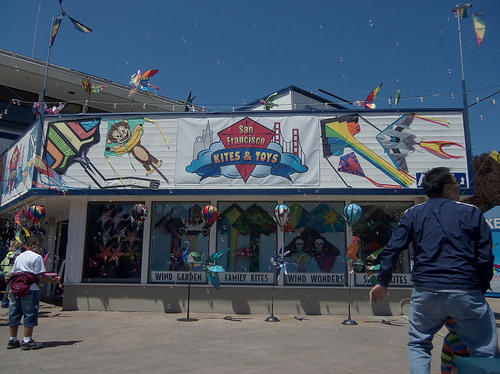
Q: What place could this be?
A: It is a store.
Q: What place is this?
A: It is a store.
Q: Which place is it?
A: It is a store.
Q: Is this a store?
A: Yes, it is a store.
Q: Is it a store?
A: Yes, it is a store.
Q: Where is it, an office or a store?
A: It is a store.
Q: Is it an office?
A: No, it is a store.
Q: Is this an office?
A: No, it is a store.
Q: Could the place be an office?
A: No, it is a store.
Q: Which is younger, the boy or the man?
A: The boy is younger than the man.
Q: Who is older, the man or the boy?
A: The man is older than the boy.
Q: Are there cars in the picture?
A: No, there are no cars.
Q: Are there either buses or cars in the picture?
A: No, there are no cars or buses.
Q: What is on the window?
A: The sign is on the window.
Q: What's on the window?
A: The sign is on the window.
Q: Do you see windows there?
A: Yes, there is a window.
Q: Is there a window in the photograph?
A: Yes, there is a window.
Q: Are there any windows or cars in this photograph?
A: Yes, there is a window.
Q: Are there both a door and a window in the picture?
A: Yes, there are both a window and a door.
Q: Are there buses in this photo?
A: No, there are no buses.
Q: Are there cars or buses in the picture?
A: No, there are no buses or cars.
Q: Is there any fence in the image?
A: No, there are no fences.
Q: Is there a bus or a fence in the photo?
A: No, there are no fences or buses.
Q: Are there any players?
A: No, there are no players.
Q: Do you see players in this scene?
A: No, there are no players.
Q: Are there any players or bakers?
A: No, there are no players or bakers.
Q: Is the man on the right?
A: Yes, the man is on the right of the image.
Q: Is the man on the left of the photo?
A: No, the man is on the right of the image.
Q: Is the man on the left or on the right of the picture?
A: The man is on the right of the image.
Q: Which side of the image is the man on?
A: The man is on the right of the image.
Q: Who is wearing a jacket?
A: The man is wearing a jacket.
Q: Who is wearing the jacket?
A: The man is wearing a jacket.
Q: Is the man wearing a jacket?
A: Yes, the man is wearing a jacket.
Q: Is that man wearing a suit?
A: No, the man is wearing a jacket.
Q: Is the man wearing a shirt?
A: Yes, the man is wearing a shirt.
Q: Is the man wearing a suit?
A: No, the man is wearing a shirt.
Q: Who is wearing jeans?
A: The man is wearing jeans.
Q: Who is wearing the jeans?
A: The man is wearing jeans.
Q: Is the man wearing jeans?
A: Yes, the man is wearing jeans.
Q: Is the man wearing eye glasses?
A: No, the man is wearing jeans.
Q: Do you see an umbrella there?
A: No, there are no umbrellas.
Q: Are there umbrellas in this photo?
A: No, there are no umbrellas.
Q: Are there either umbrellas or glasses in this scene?
A: No, there are no umbrellas or glasses.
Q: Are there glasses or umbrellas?
A: No, there are no umbrellas or glasses.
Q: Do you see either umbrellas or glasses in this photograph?
A: No, there are no umbrellas or glasses.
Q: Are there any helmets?
A: No, there are no helmets.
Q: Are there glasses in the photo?
A: No, there are no glasses.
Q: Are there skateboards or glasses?
A: No, there are no glasses or skateboards.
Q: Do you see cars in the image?
A: No, there are no cars.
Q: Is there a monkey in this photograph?
A: Yes, there is a monkey.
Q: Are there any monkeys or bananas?
A: Yes, there is a monkey.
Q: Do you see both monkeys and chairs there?
A: No, there is a monkey but no chairs.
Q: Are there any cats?
A: No, there are no cats.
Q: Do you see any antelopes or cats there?
A: No, there are no cats or antelopes.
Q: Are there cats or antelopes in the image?
A: No, there are no cats or antelopes.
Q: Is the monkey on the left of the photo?
A: Yes, the monkey is on the left of the image.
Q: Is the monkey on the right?
A: No, the monkey is on the left of the image.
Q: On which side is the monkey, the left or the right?
A: The monkey is on the left of the image.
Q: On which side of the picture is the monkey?
A: The monkey is on the left of the image.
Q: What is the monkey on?
A: The monkey is on the sign.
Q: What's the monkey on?
A: The monkey is on the sign.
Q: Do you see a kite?
A: Yes, there is a kite.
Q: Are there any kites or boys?
A: Yes, there is a kite.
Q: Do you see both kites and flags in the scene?
A: Yes, there are both a kite and a flag.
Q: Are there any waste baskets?
A: No, there are no waste baskets.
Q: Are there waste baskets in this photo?
A: No, there are no waste baskets.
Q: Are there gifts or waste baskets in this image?
A: No, there are no waste baskets or gifts.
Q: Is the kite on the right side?
A: Yes, the kite is on the right of the image.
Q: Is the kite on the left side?
A: No, the kite is on the right of the image.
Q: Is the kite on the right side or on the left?
A: The kite is on the right of the image.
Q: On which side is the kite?
A: The kite is on the right of the image.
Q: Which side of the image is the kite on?
A: The kite is on the right of the image.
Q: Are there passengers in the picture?
A: No, there are no passengers.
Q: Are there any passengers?
A: No, there are no passengers.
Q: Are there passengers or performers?
A: No, there are no passengers or performers.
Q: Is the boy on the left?
A: Yes, the boy is on the left of the image.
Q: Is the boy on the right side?
A: No, the boy is on the left of the image.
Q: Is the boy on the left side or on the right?
A: The boy is on the left of the image.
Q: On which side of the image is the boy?
A: The boy is on the left of the image.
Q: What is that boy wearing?
A: The boy is wearing a shirt.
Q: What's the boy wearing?
A: The boy is wearing a shirt.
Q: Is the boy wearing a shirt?
A: Yes, the boy is wearing a shirt.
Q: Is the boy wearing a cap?
A: No, the boy is wearing a shirt.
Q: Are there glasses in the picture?
A: No, there are no glasses.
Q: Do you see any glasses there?
A: No, there are no glasses.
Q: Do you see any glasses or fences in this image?
A: No, there are no glasses or fences.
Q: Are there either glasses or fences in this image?
A: No, there are no glasses or fences.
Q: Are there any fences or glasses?
A: No, there are no glasses or fences.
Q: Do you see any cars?
A: No, there are no cars.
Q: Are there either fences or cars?
A: No, there are no cars or fences.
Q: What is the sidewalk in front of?
A: The sidewalk is in front of the store.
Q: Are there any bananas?
A: Yes, there is a banana.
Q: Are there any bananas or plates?
A: Yes, there is a banana.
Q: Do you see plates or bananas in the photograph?
A: Yes, there is a banana.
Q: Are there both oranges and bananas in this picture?
A: No, there is a banana but no oranges.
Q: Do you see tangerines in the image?
A: No, there are no tangerines.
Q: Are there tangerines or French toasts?
A: No, there are no tangerines or French toasts.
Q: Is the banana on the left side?
A: Yes, the banana is on the left of the image.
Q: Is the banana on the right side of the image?
A: No, the banana is on the left of the image.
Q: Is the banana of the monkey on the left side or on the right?
A: The banana is on the left of the image.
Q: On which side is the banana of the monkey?
A: The banana is on the left of the image.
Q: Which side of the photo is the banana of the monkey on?
A: The banana is on the left of the image.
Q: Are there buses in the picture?
A: No, there are no buses.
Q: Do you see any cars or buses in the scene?
A: No, there are no buses or cars.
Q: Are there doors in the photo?
A: Yes, there is a door.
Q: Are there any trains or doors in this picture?
A: Yes, there is a door.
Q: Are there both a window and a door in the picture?
A: Yes, there are both a door and a window.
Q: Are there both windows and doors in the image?
A: Yes, there are both a door and a window.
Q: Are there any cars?
A: No, there are no cars.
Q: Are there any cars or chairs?
A: No, there are no cars or chairs.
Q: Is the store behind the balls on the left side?
A: Yes, the store is behind the balls.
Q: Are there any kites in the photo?
A: Yes, there is a kite.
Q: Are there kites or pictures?
A: Yes, there is a kite.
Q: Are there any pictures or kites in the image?
A: Yes, there is a kite.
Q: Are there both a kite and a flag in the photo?
A: Yes, there are both a kite and a flag.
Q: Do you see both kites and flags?
A: Yes, there are both a kite and a flag.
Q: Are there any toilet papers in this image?
A: No, there are no toilet papers.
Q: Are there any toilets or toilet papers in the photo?
A: No, there are no toilet papers or toilets.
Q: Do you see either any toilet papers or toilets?
A: No, there are no toilet papers or toilets.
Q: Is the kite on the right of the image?
A: Yes, the kite is on the right of the image.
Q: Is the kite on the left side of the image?
A: No, the kite is on the right of the image.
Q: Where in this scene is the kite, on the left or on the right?
A: The kite is on the right of the image.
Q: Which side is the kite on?
A: The kite is on the right of the image.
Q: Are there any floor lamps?
A: No, there are no floor lamps.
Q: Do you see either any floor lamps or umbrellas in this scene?
A: No, there are no floor lamps or umbrellas.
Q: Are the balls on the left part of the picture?
A: Yes, the balls are on the left of the image.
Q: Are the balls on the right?
A: No, the balls are on the left of the image.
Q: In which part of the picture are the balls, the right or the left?
A: The balls are on the left of the image.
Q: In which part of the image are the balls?
A: The balls are on the left of the image.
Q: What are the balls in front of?
A: The balls are in front of the store.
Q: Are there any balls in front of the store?
A: Yes, there are balls in front of the store.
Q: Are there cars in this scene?
A: No, there are no cars.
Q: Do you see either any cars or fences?
A: No, there are no cars or fences.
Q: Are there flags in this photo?
A: Yes, there is a flag.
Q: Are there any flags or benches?
A: Yes, there is a flag.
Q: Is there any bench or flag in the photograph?
A: Yes, there is a flag.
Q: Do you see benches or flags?
A: Yes, there is a flag.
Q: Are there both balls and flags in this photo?
A: Yes, there are both a flag and a ball.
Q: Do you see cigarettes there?
A: No, there are no cigarettes.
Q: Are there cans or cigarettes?
A: No, there are no cigarettes or cans.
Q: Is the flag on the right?
A: Yes, the flag is on the right of the image.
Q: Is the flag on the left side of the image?
A: No, the flag is on the right of the image.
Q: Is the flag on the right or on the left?
A: The flag is on the right of the image.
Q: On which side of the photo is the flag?
A: The flag is on the right of the image.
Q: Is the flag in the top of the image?
A: Yes, the flag is in the top of the image.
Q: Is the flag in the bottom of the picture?
A: No, the flag is in the top of the image.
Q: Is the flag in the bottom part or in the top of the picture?
A: The flag is in the top of the image.